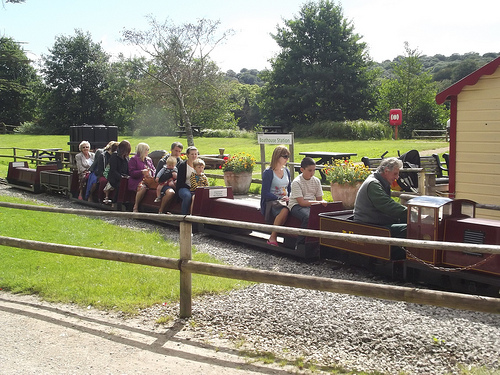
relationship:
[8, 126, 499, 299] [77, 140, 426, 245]
train for passengers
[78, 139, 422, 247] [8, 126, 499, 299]
people are on a train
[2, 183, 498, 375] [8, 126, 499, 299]
rocks are next to train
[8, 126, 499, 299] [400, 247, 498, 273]
train has a chain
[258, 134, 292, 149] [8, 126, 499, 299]
sign near train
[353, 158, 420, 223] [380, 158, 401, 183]
man has a head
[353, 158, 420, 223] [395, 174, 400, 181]
man has a nose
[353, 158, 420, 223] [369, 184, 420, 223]
man has a arm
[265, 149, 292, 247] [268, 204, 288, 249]
woman has a leg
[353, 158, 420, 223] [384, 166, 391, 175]
man has an ear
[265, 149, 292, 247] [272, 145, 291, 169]
woman has a head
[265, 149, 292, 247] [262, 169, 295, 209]
woman wearing sweater